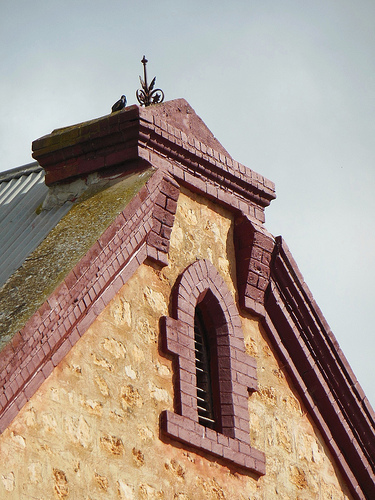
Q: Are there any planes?
A: No, there are no planes.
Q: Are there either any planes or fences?
A: No, there are no planes or fences.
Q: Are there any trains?
A: No, there are no trains.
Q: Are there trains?
A: No, there are no trains.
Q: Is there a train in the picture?
A: No, there are no trains.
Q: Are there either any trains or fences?
A: No, there are no trains or fences.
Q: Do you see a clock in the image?
A: No, there are no clocks.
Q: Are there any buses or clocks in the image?
A: No, there are no clocks or buses.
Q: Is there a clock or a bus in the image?
A: No, there are no clocks or buses.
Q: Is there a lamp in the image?
A: No, there are no lamps.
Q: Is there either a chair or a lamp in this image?
A: No, there are no lamps or chairs.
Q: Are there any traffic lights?
A: No, there are no traffic lights.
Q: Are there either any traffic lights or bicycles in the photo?
A: No, there are no traffic lights or bicycles.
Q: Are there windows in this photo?
A: Yes, there is a window.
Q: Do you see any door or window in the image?
A: Yes, there is a window.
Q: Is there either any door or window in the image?
A: Yes, there is a window.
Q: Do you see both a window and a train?
A: No, there is a window but no trains.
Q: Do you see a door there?
A: No, there are no doors.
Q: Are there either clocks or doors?
A: No, there are no doors or clocks.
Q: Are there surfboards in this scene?
A: No, there are no surfboards.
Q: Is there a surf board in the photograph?
A: No, there are no surfboards.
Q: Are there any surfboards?
A: No, there are no surfboards.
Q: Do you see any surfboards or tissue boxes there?
A: No, there are no surfboards or tissue boxes.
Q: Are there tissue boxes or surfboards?
A: No, there are no surfboards or tissue boxes.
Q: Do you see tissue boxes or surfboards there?
A: No, there are no surfboards or tissue boxes.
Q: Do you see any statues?
A: No, there are no statues.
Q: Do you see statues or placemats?
A: No, there are no statues or placemats.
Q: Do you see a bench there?
A: No, there are no benches.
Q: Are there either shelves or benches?
A: No, there are no benches or shelves.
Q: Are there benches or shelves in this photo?
A: No, there are no benches or shelves.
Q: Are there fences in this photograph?
A: No, there are no fences.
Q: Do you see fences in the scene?
A: No, there are no fences.